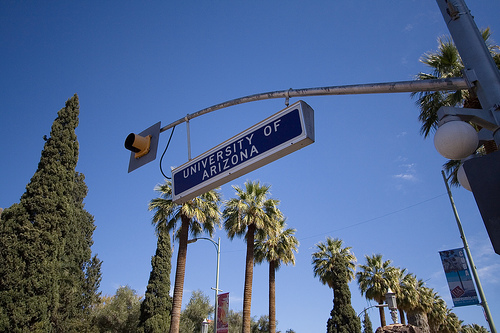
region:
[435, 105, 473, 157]
a white street light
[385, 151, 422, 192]
a cloud in the sky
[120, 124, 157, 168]
a traffic light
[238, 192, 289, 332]
several palm trees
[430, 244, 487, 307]
a banner on street pole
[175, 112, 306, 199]
A blue and white sign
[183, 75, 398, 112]
a pole for traffic light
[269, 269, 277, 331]
trunk on the tree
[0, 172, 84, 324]
leaves on the tree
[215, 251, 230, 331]
a red sign on pole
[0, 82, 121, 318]
tall skinny tipped pine tree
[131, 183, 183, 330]
very narrow pine tree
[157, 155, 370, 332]
palm trees around pine trees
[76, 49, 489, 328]
university of arizona road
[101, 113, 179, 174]
traffic alert light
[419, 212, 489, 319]
blue flag on light post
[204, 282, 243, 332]
red flag on light post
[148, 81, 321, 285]
street sign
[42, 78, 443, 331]
bright blue skies behind palm trees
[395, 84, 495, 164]
round white light on post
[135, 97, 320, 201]
blue sign that reads University of Arizona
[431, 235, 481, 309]
decorative flag sign depicting blue colors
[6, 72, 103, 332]
group of evergreen trees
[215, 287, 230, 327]
decorative flag sign depicting red colors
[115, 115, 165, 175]
caution light at the end of a long pole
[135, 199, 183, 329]
Evergreen trees between the group of evergreen trees and the palm trees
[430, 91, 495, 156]
City lamp with a white round globe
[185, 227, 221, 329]
typical city street light on a pole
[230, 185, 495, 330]
row of palm trees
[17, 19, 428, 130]
cloudless clear blue sky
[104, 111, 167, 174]
A single street light sits at the end of a pole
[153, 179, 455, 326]
Palm trees lined up in a row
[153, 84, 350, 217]
A blue sign for the University of Arizona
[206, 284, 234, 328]
A red banner hangs on a light pole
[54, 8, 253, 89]
A beautiful blue sky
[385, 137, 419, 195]
A few small clouds in the distance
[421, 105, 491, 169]
A white globe light cover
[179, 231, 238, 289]
A street light sits between the tall trees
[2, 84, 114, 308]
The tree narrows and points to the sky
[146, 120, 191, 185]
A wire runs from the pole to the sign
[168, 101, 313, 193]
Blue and white street sign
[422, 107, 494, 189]
white and grey street lights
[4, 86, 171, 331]
triangular shaped green trees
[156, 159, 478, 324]
row of green and yellow palm trees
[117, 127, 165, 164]
grey and yellow traffic light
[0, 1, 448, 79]
blue sky with small clouds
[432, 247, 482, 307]
blue and white flag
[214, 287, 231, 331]
red and white flag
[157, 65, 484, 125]
grey metal traffic light pole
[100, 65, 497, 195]
traffic light with blue and white street sign